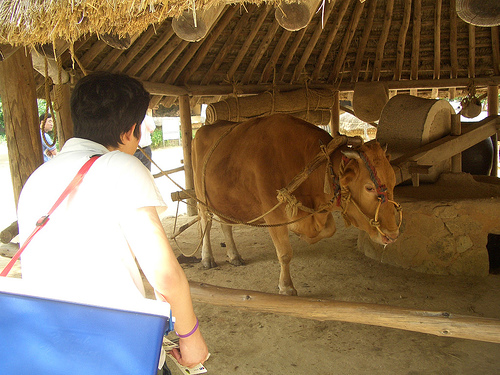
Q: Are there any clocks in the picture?
A: No, there are no clocks.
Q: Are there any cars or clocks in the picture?
A: No, there are no clocks or cars.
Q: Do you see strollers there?
A: No, there are no strollers.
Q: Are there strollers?
A: No, there are no strollers.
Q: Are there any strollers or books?
A: No, there are no strollers or books.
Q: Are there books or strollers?
A: No, there are no strollers or books.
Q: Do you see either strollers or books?
A: No, there are no strollers or books.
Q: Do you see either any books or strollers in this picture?
A: No, there are no strollers or books.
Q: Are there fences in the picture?
A: No, there are no fences.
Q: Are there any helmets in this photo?
A: No, there are no helmets.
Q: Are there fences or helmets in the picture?
A: No, there are no helmets or fences.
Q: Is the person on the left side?
A: Yes, the person is on the left of the image.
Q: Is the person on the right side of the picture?
A: No, the person is on the left of the image.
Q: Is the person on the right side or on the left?
A: The person is on the left of the image.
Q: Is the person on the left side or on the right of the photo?
A: The person is on the left of the image.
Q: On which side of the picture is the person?
A: The person is on the left of the image.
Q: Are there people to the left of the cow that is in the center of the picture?
A: Yes, there is a person to the left of the cow.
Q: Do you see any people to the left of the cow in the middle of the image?
A: Yes, there is a person to the left of the cow.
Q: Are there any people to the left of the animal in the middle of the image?
A: Yes, there is a person to the left of the cow.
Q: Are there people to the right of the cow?
A: No, the person is to the left of the cow.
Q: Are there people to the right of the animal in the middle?
A: No, the person is to the left of the cow.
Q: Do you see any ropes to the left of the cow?
A: No, there is a person to the left of the cow.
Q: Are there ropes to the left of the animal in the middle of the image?
A: No, there is a person to the left of the cow.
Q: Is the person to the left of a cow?
A: Yes, the person is to the left of a cow.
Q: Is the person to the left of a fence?
A: No, the person is to the left of a cow.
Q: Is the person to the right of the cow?
A: No, the person is to the left of the cow.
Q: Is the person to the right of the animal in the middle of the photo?
A: No, the person is to the left of the cow.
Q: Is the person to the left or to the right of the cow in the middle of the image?
A: The person is to the left of the cow.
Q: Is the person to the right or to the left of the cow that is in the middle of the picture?
A: The person is to the left of the cow.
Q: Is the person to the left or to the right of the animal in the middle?
A: The person is to the left of the cow.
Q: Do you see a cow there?
A: Yes, there is a cow.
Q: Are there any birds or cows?
A: Yes, there is a cow.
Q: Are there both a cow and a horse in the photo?
A: No, there is a cow but no horses.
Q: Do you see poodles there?
A: No, there are no poodles.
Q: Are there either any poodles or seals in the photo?
A: No, there are no poodles or seals.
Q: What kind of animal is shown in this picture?
A: The animal is a cow.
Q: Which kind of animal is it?
A: The animal is a cow.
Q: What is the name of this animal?
A: This is a cow.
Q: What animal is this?
A: This is a cow.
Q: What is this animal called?
A: This is a cow.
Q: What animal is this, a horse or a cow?
A: This is a cow.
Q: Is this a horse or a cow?
A: This is a cow.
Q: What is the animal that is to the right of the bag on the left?
A: The animal is a cow.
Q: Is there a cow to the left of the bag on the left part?
A: No, the cow is to the right of the bag.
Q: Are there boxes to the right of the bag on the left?
A: No, there is a cow to the right of the bag.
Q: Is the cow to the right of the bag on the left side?
A: Yes, the cow is to the right of the bag.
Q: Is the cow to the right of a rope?
A: No, the cow is to the right of the bag.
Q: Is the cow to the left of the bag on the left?
A: No, the cow is to the right of the bag.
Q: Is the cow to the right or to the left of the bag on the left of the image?
A: The cow is to the right of the bag.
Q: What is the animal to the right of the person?
A: The animal is a cow.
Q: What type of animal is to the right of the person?
A: The animal is a cow.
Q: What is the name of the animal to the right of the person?
A: The animal is a cow.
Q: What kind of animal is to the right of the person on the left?
A: The animal is a cow.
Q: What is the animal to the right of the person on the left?
A: The animal is a cow.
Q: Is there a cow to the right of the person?
A: Yes, there is a cow to the right of the person.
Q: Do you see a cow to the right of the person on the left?
A: Yes, there is a cow to the right of the person.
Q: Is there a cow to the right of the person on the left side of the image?
A: Yes, there is a cow to the right of the person.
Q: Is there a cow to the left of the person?
A: No, the cow is to the right of the person.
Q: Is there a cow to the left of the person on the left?
A: No, the cow is to the right of the person.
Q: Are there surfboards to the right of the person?
A: No, there is a cow to the right of the person.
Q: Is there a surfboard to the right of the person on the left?
A: No, there is a cow to the right of the person.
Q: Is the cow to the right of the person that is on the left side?
A: Yes, the cow is to the right of the person.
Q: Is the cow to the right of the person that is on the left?
A: Yes, the cow is to the right of the person.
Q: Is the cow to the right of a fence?
A: No, the cow is to the right of the person.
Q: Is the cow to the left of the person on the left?
A: No, the cow is to the right of the person.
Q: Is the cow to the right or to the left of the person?
A: The cow is to the right of the person.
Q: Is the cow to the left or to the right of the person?
A: The cow is to the right of the person.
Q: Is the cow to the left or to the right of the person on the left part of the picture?
A: The cow is to the right of the person.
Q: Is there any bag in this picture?
A: Yes, there is a bag.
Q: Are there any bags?
A: Yes, there is a bag.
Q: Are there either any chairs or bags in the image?
A: Yes, there is a bag.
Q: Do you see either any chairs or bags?
A: Yes, there is a bag.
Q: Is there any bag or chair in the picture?
A: Yes, there is a bag.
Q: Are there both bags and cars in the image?
A: No, there is a bag but no cars.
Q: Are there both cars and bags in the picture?
A: No, there is a bag but no cars.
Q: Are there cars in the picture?
A: No, there are no cars.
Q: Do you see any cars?
A: No, there are no cars.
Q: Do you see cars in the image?
A: No, there are no cars.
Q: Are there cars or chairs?
A: No, there are no cars or chairs.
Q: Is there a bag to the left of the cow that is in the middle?
A: Yes, there is a bag to the left of the cow.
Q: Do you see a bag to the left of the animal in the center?
A: Yes, there is a bag to the left of the cow.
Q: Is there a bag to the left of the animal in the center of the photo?
A: Yes, there is a bag to the left of the cow.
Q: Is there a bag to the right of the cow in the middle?
A: No, the bag is to the left of the cow.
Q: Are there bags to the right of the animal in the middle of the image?
A: No, the bag is to the left of the cow.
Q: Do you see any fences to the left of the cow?
A: No, there is a bag to the left of the cow.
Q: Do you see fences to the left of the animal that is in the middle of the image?
A: No, there is a bag to the left of the cow.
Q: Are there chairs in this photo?
A: No, there are no chairs.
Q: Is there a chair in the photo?
A: No, there are no chairs.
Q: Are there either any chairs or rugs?
A: No, there are no chairs or rugs.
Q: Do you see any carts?
A: No, there are no carts.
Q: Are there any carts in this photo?
A: No, there are no carts.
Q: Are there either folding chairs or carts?
A: No, there are no carts or folding chairs.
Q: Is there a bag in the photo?
A: Yes, there is a bag.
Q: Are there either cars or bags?
A: Yes, there is a bag.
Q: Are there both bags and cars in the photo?
A: No, there is a bag but no cars.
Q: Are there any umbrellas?
A: No, there are no umbrellas.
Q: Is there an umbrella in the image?
A: No, there are no umbrellas.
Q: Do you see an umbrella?
A: No, there are no umbrellas.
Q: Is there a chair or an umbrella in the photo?
A: No, there are no umbrellas or chairs.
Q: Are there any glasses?
A: No, there are no glasses.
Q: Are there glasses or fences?
A: No, there are no glasses or fences.